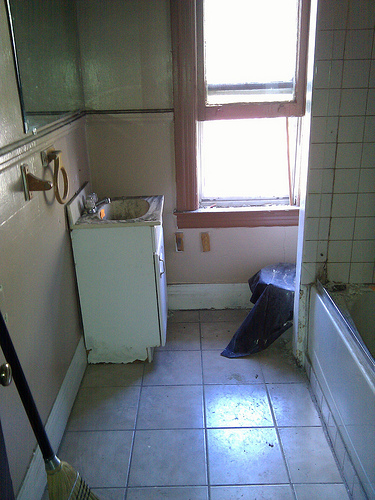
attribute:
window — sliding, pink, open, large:
[171, 10, 308, 228]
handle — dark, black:
[2, 322, 57, 462]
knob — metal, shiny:
[0, 364, 14, 394]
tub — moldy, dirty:
[327, 280, 374, 334]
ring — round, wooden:
[40, 152, 74, 202]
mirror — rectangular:
[29, 2, 170, 118]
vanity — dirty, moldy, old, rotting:
[79, 192, 171, 364]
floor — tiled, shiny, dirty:
[100, 359, 334, 492]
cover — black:
[256, 266, 314, 325]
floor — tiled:
[71, 339, 337, 495]